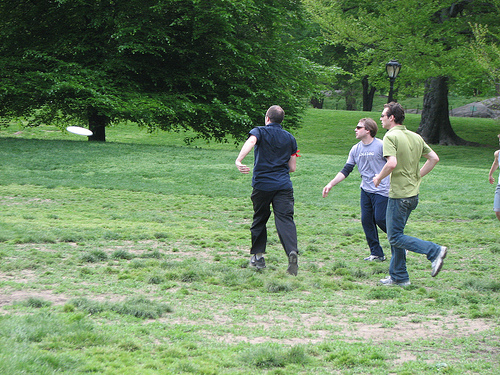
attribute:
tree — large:
[19, 17, 304, 124]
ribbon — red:
[291, 150, 301, 157]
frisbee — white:
[65, 120, 95, 139]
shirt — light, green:
[381, 126, 432, 199]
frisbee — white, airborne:
[53, 110, 115, 151]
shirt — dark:
[246, 122, 296, 192]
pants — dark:
[382, 192, 435, 278]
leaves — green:
[82, 21, 309, 162]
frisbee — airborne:
[61, 117, 102, 150]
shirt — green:
[377, 135, 418, 176]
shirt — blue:
[250, 126, 300, 194]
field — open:
[0, 105, 497, 374]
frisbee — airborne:
[48, 95, 113, 180]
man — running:
[211, 56, 351, 286]